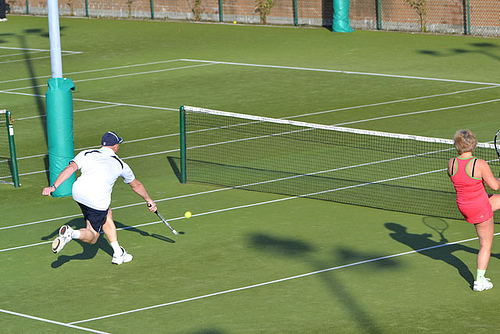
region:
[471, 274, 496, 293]
Woman wearing shoes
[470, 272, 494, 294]
Woman is wearing shoes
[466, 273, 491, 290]
Woman wearing white shoes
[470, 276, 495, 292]
Woman is wearing white shoes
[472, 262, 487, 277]
Woman wearing socks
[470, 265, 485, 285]
Woman is wearing socks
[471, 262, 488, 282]
Woman wearing white socks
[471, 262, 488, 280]
Woman is wearing white socks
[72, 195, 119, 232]
Man is wearing shorts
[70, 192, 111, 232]
Man is wearing blue shorts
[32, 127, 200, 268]
man hitting a tennis ball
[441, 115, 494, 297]
a woman playing tennis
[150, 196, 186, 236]
tennis racket in the man's right hand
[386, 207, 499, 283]
shadow on the ground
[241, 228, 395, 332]
shadow of a light post on the ground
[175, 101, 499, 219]
tennis court net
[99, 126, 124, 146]
blue hat on the man's head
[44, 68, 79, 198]
padded pole in between two courts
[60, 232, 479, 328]
white line painted on the court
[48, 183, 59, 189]
watch on the man's left wrist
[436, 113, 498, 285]
A lady tennis player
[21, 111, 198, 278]
A man playng tennis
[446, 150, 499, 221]
A woman wearing pink outfit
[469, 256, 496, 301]
A white tennis shoe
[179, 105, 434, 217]
A black and white tennis net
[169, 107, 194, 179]
A green metal post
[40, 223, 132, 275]
White and black tennis shoes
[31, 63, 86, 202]
A green padding around pole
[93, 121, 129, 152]
A blue baseball cap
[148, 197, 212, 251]
A yellow tennis ball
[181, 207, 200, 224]
Tennis ball in flight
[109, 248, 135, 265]
Foot of tennis player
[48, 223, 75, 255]
Foot of tennis player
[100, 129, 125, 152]
Head of tennis player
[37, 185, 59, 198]
Hand of tennis player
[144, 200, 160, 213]
Hand of tennis player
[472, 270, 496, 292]
foot of tennis player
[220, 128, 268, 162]
Part of tennis net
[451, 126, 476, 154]
Head of tennis player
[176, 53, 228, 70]
White line of tennis court